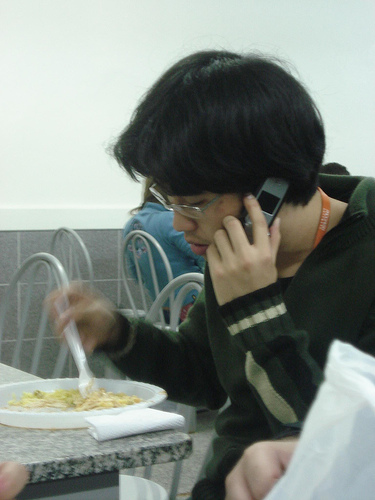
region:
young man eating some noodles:
[41, 50, 373, 498]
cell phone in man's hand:
[237, 176, 288, 244]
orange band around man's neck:
[312, 186, 330, 249]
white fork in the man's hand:
[53, 292, 95, 395]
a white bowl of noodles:
[0, 373, 166, 430]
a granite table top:
[0, 359, 192, 489]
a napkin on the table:
[82, 405, 183, 442]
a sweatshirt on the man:
[98, 171, 372, 497]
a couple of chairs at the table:
[1, 252, 205, 395]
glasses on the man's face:
[149, 181, 224, 217]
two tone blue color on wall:
[71, 27, 176, 55]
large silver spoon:
[43, 292, 97, 406]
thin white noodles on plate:
[35, 385, 112, 413]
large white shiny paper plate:
[9, 368, 170, 430]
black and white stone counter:
[67, 440, 155, 471]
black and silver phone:
[239, 178, 305, 252]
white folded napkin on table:
[85, 407, 211, 440]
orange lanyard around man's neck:
[300, 169, 346, 244]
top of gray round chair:
[24, 218, 108, 287]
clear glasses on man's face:
[136, 178, 237, 218]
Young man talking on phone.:
[36, 26, 361, 372]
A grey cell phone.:
[244, 163, 298, 236]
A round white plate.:
[8, 370, 171, 422]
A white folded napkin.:
[81, 406, 191, 438]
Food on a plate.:
[15, 375, 137, 411]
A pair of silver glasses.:
[132, 168, 222, 224]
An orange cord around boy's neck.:
[297, 173, 343, 263]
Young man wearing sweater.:
[111, 168, 373, 411]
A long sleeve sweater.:
[88, 176, 363, 437]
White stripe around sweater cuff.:
[215, 283, 305, 354]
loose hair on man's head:
[244, 40, 304, 88]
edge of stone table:
[76, 439, 169, 472]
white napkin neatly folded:
[83, 399, 188, 441]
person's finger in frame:
[211, 449, 304, 497]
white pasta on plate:
[54, 384, 117, 402]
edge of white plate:
[38, 406, 79, 424]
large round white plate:
[6, 361, 170, 432]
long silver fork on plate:
[44, 283, 104, 411]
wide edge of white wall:
[24, 191, 93, 221]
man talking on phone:
[180, 174, 306, 267]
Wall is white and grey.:
[27, 49, 113, 267]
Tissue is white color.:
[79, 405, 184, 441]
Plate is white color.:
[4, 367, 95, 420]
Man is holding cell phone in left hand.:
[183, 81, 321, 416]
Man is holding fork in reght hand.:
[46, 285, 125, 398]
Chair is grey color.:
[8, 237, 152, 290]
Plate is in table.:
[17, 387, 94, 447]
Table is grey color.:
[2, 430, 84, 465]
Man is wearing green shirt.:
[163, 243, 326, 409]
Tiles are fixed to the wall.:
[1, 240, 141, 329]